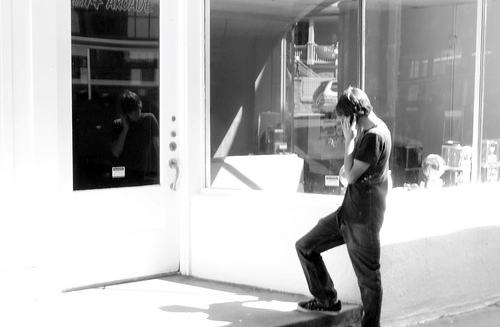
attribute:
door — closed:
[47, 5, 192, 265]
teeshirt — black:
[328, 127, 397, 226]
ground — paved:
[121, 268, 299, 324]